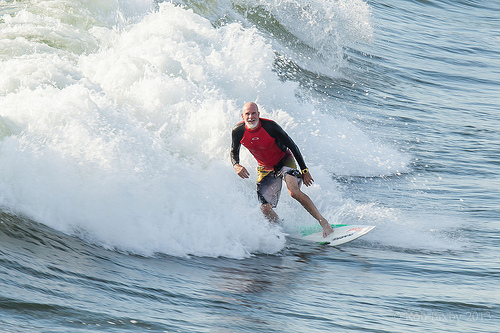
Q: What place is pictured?
A: It is an ocean.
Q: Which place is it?
A: It is an ocean.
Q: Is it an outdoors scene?
A: Yes, it is outdoors.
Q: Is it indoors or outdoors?
A: It is outdoors.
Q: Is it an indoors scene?
A: No, it is outdoors.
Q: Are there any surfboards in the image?
A: Yes, there is a surfboard.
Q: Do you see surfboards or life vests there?
A: Yes, there is a surfboard.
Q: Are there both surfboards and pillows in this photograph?
A: No, there is a surfboard but no pillows.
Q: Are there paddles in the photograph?
A: No, there are no paddles.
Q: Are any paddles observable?
A: No, there are no paddles.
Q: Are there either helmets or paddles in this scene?
A: No, there are no paddles or helmets.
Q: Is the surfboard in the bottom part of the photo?
A: Yes, the surfboard is in the bottom of the image.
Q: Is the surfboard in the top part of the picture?
A: No, the surfboard is in the bottom of the image.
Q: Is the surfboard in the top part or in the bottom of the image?
A: The surfboard is in the bottom of the image.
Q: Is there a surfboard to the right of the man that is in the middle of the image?
A: Yes, there is a surfboard to the right of the man.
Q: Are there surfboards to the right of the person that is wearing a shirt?
A: Yes, there is a surfboard to the right of the man.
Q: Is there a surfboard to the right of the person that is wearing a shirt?
A: Yes, there is a surfboard to the right of the man.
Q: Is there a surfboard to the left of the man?
A: No, the surfboard is to the right of the man.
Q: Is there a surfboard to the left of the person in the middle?
A: No, the surfboard is to the right of the man.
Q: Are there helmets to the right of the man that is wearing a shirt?
A: No, there is a surfboard to the right of the man.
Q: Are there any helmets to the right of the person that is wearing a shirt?
A: No, there is a surfboard to the right of the man.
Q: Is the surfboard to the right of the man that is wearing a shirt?
A: Yes, the surfboard is to the right of the man.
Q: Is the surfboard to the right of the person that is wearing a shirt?
A: Yes, the surfboard is to the right of the man.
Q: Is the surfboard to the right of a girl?
A: No, the surfboard is to the right of the man.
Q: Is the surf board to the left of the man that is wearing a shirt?
A: No, the surf board is to the right of the man.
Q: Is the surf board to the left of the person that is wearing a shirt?
A: No, the surf board is to the right of the man.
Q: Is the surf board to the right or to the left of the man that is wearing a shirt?
A: The surf board is to the right of the man.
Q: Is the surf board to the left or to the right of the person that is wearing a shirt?
A: The surf board is to the right of the man.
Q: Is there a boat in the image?
A: No, there are no boats.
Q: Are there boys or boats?
A: No, there are no boats or boys.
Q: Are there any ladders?
A: No, there are no ladders.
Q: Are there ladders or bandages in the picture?
A: No, there are no ladders or bandages.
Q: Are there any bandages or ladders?
A: No, there are no ladders or bandages.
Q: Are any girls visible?
A: No, there are no girls.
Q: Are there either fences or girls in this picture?
A: No, there are no girls or fences.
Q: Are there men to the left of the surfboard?
A: Yes, there is a man to the left of the surfboard.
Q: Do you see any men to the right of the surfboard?
A: No, the man is to the left of the surfboard.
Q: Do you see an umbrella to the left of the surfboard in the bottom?
A: No, there is a man to the left of the surfboard.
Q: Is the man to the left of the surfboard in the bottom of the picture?
A: Yes, the man is to the left of the surfboard.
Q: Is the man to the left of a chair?
A: No, the man is to the left of the surfboard.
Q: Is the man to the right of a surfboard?
A: No, the man is to the left of a surfboard.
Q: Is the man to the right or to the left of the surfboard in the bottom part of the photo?
A: The man is to the left of the surf board.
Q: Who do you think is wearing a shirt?
A: The man is wearing a shirt.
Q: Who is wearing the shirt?
A: The man is wearing a shirt.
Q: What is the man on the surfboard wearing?
A: The man is wearing a shirt.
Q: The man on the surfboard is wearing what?
A: The man is wearing a shirt.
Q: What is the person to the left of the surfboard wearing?
A: The man is wearing a shirt.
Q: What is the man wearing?
A: The man is wearing a shirt.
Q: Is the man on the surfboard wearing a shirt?
A: Yes, the man is wearing a shirt.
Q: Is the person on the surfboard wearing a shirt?
A: Yes, the man is wearing a shirt.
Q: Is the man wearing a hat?
A: No, the man is wearing a shirt.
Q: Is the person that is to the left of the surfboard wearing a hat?
A: No, the man is wearing a shirt.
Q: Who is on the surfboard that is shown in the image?
A: The man is on the surfboard.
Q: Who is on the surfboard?
A: The man is on the surfboard.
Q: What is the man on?
A: The man is on the surfboard.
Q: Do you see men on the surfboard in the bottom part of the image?
A: Yes, there is a man on the surfboard.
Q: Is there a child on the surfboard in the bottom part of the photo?
A: No, there is a man on the surfboard.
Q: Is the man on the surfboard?
A: Yes, the man is on the surfboard.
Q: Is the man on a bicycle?
A: No, the man is on the surfboard.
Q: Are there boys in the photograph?
A: No, there are no boys.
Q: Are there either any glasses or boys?
A: No, there are no boys or glasses.